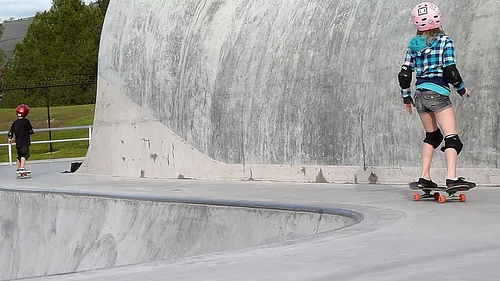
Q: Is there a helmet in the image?
A: Yes, there is a helmet.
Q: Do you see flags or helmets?
A: Yes, there is a helmet.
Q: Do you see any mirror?
A: No, there are no mirrors.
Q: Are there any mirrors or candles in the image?
A: No, there are no mirrors or candles.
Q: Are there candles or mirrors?
A: No, there are no mirrors or candles.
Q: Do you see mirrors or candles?
A: No, there are no mirrors or candles.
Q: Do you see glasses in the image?
A: No, there are no glasses.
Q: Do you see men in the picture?
A: No, there are no men.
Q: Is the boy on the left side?
A: Yes, the boy is on the left of the image.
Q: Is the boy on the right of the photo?
A: No, the boy is on the left of the image.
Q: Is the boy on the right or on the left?
A: The boy is on the left of the image.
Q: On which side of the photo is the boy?
A: The boy is on the left of the image.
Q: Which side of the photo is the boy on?
A: The boy is on the left of the image.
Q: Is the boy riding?
A: Yes, the boy is riding.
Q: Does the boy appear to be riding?
A: Yes, the boy is riding.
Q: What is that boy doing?
A: The boy is riding.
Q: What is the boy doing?
A: The boy is riding.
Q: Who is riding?
A: The boy is riding.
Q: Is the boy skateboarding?
A: No, the boy is riding.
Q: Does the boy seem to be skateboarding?
A: No, the boy is riding.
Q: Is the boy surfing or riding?
A: The boy is riding.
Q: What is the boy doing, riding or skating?
A: The boy is riding.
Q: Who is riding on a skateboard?
A: The boy is riding on a skateboard.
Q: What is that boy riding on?
A: The boy is riding on a skateboard.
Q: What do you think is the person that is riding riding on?
A: The boy is riding on a skateboard.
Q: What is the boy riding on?
A: The boy is riding on a skateboard.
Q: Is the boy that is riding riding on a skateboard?
A: Yes, the boy is riding on a skateboard.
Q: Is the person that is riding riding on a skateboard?
A: Yes, the boy is riding on a skateboard.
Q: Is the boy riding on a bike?
A: No, the boy is riding on a skateboard.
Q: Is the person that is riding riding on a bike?
A: No, the boy is riding on a skateboard.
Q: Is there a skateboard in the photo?
A: Yes, there are skateboards.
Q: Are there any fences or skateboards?
A: Yes, there are skateboards.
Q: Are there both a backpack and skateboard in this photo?
A: No, there are skateboards but no backpacks.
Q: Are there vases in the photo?
A: No, there are no vases.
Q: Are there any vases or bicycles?
A: No, there are no vases or bicycles.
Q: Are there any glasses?
A: No, there are no glasses.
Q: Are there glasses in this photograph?
A: No, there are no glasses.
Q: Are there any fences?
A: Yes, there is a fence.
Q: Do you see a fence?
A: Yes, there is a fence.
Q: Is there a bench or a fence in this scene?
A: Yes, there is a fence.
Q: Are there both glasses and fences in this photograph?
A: No, there is a fence but no glasses.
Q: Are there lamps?
A: No, there are no lamps.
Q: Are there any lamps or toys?
A: No, there are no lamps or toys.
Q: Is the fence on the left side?
A: Yes, the fence is on the left of the image.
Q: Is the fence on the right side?
A: No, the fence is on the left of the image.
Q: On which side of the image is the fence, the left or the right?
A: The fence is on the left of the image.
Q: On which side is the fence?
A: The fence is on the left of the image.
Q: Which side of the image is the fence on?
A: The fence is on the left of the image.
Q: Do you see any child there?
A: Yes, there are children.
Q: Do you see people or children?
A: Yes, there are children.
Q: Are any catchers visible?
A: No, there are no catchers.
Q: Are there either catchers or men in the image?
A: No, there are no catchers or men.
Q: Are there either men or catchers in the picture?
A: No, there are no catchers or men.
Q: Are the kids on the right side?
A: Yes, the kids are on the right of the image.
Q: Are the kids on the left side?
A: No, the kids are on the right of the image.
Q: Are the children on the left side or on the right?
A: The children are on the right of the image.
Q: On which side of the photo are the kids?
A: The kids are on the right of the image.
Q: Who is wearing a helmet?
A: The kids are wearing a helmet.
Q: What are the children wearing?
A: The children are wearing a helmet.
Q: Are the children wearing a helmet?
A: Yes, the children are wearing a helmet.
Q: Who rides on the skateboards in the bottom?
A: The children ride on the skateboards.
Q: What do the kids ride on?
A: The kids ride on the skateboards.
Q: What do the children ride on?
A: The kids ride on the skateboards.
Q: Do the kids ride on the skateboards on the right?
A: Yes, the kids ride on the skateboards.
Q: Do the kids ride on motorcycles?
A: No, the kids ride on the skateboards.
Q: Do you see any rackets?
A: No, there are no rackets.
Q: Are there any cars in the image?
A: No, there are no cars.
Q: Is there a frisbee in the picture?
A: No, there are no frisbees.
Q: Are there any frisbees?
A: No, there are no frisbees.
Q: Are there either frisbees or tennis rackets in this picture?
A: No, there are no frisbees or tennis rackets.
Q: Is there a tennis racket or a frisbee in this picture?
A: No, there are no frisbees or rackets.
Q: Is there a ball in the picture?
A: No, there are no balls.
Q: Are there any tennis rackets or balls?
A: No, there are no balls or tennis rackets.